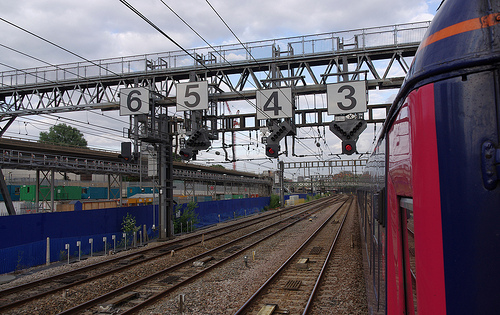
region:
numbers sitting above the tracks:
[113, 84, 372, 132]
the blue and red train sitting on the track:
[353, 1, 498, 311]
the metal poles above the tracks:
[1, 22, 389, 113]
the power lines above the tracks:
[1, 4, 235, 59]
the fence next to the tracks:
[3, 192, 293, 257]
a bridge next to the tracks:
[1, 133, 283, 193]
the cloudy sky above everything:
[5, 0, 444, 45]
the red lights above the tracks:
[180, 125, 372, 159]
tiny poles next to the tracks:
[58, 224, 150, 259]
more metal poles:
[273, 158, 364, 200]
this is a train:
[385, 85, 484, 313]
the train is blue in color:
[443, 93, 492, 186]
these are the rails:
[212, 224, 339, 296]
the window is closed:
[387, 203, 426, 305]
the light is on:
[341, 135, 358, 155]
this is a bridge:
[215, 38, 297, 87]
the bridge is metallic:
[298, 32, 347, 82]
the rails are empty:
[223, 202, 348, 306]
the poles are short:
[62, 227, 147, 261]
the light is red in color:
[343, 142, 352, 152]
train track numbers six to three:
[108, 81, 380, 114]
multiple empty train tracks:
[3, 192, 358, 312]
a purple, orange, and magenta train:
[361, 7, 499, 314]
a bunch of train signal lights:
[139, 121, 379, 163]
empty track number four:
[230, 180, 365, 310]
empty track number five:
[62, 191, 342, 311]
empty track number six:
[1, 190, 345, 313]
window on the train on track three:
[393, 195, 438, 310]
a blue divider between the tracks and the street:
[2, 195, 321, 272]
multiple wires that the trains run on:
[121, 1, 341, 168]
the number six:
[107, 81, 159, 135]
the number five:
[170, 67, 212, 127]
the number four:
[250, 78, 304, 158]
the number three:
[328, 67, 383, 138]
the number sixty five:
[97, 75, 221, 133]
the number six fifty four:
[84, 62, 301, 160]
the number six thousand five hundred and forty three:
[105, 62, 382, 137]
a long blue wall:
[14, 167, 306, 259]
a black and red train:
[377, 25, 475, 279]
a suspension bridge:
[8, 28, 408, 133]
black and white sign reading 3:
[328, 83, 367, 111]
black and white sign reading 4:
[256, 88, 293, 117]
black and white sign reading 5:
[176, 83, 208, 109]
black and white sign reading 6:
[119, 89, 147, 114]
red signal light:
[341, 142, 355, 152]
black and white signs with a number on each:
[115, 80, 368, 119]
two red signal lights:
[260, 145, 362, 157]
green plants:
[122, 214, 139, 244]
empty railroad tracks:
[3, 191, 363, 314]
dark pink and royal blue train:
[360, 0, 497, 312]